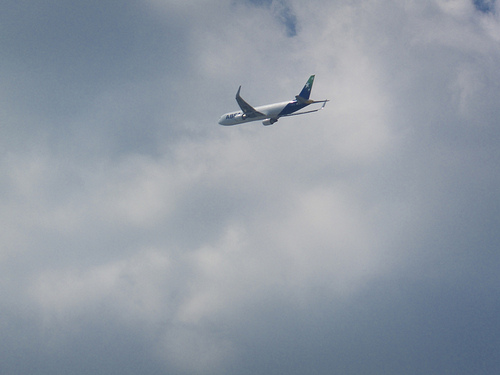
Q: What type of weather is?
A: It is cloudy.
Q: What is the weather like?
A: It is cloudy.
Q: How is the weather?
A: It is cloudy.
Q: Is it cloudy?
A: Yes, it is cloudy.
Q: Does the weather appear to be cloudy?
A: Yes, it is cloudy.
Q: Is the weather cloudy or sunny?
A: It is cloudy.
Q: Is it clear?
A: No, it is cloudy.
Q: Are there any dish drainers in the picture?
A: No, there are no dish drainers.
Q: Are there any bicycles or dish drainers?
A: No, there are no dish drainers or bicycles.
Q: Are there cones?
A: No, there are no cones.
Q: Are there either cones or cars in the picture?
A: No, there are no cones or cars.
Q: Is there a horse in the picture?
A: No, there are no horses.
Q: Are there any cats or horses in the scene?
A: No, there are no horses or cats.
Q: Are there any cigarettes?
A: No, there are no cigarettes.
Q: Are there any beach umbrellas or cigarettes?
A: No, there are no cigarettes or beach umbrellas.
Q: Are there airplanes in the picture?
A: Yes, there is an airplane.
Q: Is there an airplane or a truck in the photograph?
A: Yes, there is an airplane.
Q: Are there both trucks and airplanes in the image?
A: No, there is an airplane but no trucks.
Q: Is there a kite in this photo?
A: No, there are no kites.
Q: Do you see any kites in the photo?
A: No, there are no kites.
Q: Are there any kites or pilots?
A: No, there are no kites or pilots.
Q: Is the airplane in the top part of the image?
A: Yes, the airplane is in the top of the image.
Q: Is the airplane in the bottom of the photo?
A: No, the airplane is in the top of the image.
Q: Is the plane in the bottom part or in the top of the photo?
A: The plane is in the top of the image.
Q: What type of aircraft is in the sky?
A: The aircraft is an airplane.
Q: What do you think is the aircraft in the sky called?
A: The aircraft is an airplane.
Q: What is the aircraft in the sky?
A: The aircraft is an airplane.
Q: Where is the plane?
A: The plane is in the sky.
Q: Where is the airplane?
A: The plane is in the sky.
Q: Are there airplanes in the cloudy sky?
A: Yes, there is an airplane in the sky.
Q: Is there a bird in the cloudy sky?
A: No, there is an airplane in the sky.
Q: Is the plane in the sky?
A: Yes, the plane is in the sky.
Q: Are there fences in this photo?
A: No, there are no fences.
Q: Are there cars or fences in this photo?
A: No, there are no fences or cars.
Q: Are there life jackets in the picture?
A: No, there are no life jackets.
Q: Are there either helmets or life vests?
A: No, there are no life vests or helmets.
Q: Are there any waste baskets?
A: No, there are no waste baskets.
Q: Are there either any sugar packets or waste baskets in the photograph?
A: No, there are no waste baskets or sugar packets.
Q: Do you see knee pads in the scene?
A: No, there are no knee pads.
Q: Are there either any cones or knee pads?
A: No, there are no knee pads or cones.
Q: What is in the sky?
A: The clouds are in the sky.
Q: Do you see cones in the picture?
A: No, there are no cones.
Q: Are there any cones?
A: No, there are no cones.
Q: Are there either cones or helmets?
A: No, there are no cones or helmets.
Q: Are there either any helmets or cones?
A: No, there are no cones or helmets.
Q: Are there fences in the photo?
A: No, there are no fences.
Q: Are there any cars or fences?
A: No, there are no fences or cars.